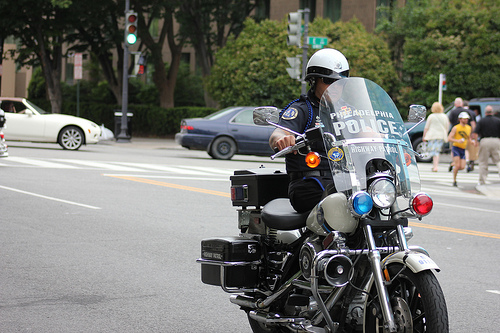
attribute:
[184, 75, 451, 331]
motorcycle — for police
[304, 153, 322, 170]
light — orange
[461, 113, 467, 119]
hat — white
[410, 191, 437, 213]
light — red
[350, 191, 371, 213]
light — red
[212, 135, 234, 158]
tire — black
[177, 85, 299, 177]
care — blue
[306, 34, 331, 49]
street sign — green, white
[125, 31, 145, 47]
light — green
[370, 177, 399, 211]
light — white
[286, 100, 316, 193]
uniform — man's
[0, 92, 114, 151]
car — white